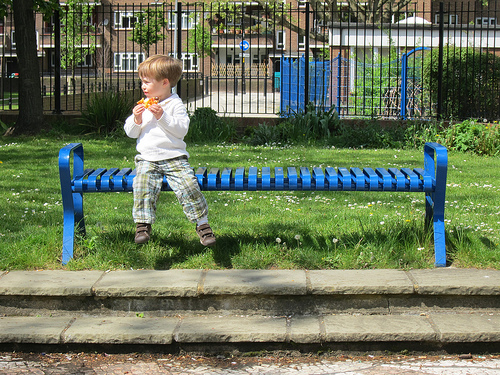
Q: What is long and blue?
A: The bench.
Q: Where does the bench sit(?
A: A section of green grass.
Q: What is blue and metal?
A: The bench.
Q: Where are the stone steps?
A: In front of the bench.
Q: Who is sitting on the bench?
A: A little boy.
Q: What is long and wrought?
A: The iron fence.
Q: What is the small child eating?
A: Pizza.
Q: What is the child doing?
A: Sitting.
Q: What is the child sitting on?
A: A blue bench.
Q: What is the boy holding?
A: Food.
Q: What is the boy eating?
A: Pizza.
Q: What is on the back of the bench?
A: Nothing.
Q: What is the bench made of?
A: Metal.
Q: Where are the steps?
A: Before the bench.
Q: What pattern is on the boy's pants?
A: Plaid.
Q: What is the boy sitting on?
A: A bench.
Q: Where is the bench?
A: On the grass.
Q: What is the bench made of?
A: Metal.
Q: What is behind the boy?
A: A fence.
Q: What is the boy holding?
A: Food.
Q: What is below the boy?
A: Grass.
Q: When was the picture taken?
A: Daytime.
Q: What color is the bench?
A: Blue.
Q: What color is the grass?
A: Green.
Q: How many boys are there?
A: One.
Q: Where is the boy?
A: On the bench.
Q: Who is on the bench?
A: The boy.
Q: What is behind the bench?
A: Grass.